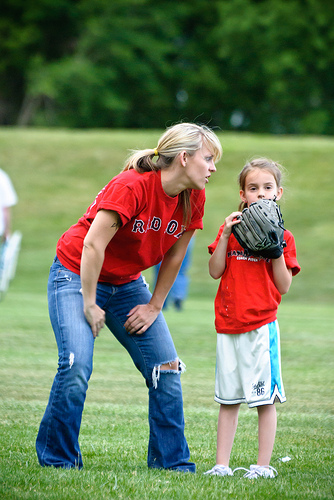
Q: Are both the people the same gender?
A: Yes, all the people are female.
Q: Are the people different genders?
A: No, all the people are female.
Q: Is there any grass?
A: Yes, there is grass.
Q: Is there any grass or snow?
A: Yes, there is grass.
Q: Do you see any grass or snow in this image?
A: Yes, there is grass.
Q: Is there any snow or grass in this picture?
A: Yes, there is grass.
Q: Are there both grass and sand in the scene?
A: No, there is grass but no sand.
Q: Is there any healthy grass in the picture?
A: Yes, there is healthy grass.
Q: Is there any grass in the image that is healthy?
A: Yes, there is grass that is healthy.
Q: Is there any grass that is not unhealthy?
A: Yes, there is healthy grass.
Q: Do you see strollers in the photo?
A: No, there are no strollers.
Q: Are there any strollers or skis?
A: No, there are no strollers or skis.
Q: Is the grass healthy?
A: Yes, the grass is healthy.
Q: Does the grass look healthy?
A: Yes, the grass is healthy.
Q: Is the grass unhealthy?
A: No, the grass is healthy.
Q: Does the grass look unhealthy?
A: No, the grass is healthy.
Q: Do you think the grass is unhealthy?
A: No, the grass is healthy.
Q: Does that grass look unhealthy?
A: No, the grass is healthy.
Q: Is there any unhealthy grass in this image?
A: No, there is grass but it is healthy.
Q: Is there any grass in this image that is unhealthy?
A: No, there is grass but it is healthy.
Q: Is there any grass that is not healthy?
A: No, there is grass but it is healthy.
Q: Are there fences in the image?
A: No, there are no fences.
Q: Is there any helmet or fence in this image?
A: No, there are no fences or helmets.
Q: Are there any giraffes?
A: No, there are no giraffes.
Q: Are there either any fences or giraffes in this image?
A: No, there are no giraffes or fences.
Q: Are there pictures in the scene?
A: No, there are no pictures.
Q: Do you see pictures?
A: No, there are no pictures.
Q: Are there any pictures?
A: No, there are no pictures.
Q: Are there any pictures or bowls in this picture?
A: No, there are no pictures or bowls.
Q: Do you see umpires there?
A: No, there are no umpires.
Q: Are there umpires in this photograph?
A: No, there are no umpires.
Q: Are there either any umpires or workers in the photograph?
A: No, there are no umpires or workers.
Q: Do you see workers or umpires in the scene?
A: No, there are no umpires or workers.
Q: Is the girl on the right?
A: Yes, the girl is on the right of the image.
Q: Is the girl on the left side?
A: No, the girl is on the right of the image.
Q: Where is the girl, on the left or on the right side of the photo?
A: The girl is on the right of the image.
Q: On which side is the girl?
A: The girl is on the right of the image.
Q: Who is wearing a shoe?
A: The girl is wearing a shoe.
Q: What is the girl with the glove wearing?
A: The girl is wearing a shoe.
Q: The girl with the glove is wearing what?
A: The girl is wearing a shoe.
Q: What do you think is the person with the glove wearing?
A: The girl is wearing a shoe.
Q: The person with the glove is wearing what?
A: The girl is wearing a shoe.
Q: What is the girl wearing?
A: The girl is wearing a shoe.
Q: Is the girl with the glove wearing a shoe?
A: Yes, the girl is wearing a shoe.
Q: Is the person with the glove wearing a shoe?
A: Yes, the girl is wearing a shoe.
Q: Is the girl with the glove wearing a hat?
A: No, the girl is wearing a shoe.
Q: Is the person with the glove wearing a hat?
A: No, the girl is wearing a shoe.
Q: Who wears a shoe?
A: The girl wears a shoe.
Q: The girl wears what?
A: The girl wears a shoe.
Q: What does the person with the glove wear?
A: The girl wears a shoe.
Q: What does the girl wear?
A: The girl wears a shoe.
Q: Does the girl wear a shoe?
A: Yes, the girl wears a shoe.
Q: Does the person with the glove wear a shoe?
A: Yes, the girl wears a shoe.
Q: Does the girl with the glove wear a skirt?
A: No, the girl wears a shoe.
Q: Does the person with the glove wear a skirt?
A: No, the girl wears a shoe.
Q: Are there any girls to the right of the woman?
A: Yes, there is a girl to the right of the woman.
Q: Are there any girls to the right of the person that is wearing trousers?
A: Yes, there is a girl to the right of the woman.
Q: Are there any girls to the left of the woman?
A: No, the girl is to the right of the woman.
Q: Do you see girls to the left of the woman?
A: No, the girl is to the right of the woman.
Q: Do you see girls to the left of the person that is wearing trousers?
A: No, the girl is to the right of the woman.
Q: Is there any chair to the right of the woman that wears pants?
A: No, there is a girl to the right of the woman.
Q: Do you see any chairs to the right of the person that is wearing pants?
A: No, there is a girl to the right of the woman.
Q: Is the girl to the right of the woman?
A: Yes, the girl is to the right of the woman.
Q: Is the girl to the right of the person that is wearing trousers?
A: Yes, the girl is to the right of the woman.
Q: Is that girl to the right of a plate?
A: No, the girl is to the right of the woman.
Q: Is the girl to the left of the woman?
A: No, the girl is to the right of the woman.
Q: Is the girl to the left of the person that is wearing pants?
A: No, the girl is to the right of the woman.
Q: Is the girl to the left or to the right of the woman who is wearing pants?
A: The girl is to the right of the woman.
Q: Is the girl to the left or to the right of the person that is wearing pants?
A: The girl is to the right of the woman.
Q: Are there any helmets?
A: No, there are no helmets.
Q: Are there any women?
A: Yes, there is a woman.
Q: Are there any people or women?
A: Yes, there is a woman.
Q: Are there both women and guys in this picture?
A: No, there is a woman but no guys.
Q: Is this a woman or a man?
A: This is a woman.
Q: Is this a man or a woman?
A: This is a woman.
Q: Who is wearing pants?
A: The woman is wearing pants.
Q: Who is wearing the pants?
A: The woman is wearing pants.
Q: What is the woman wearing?
A: The woman is wearing trousers.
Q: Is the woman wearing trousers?
A: Yes, the woman is wearing trousers.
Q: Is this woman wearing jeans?
A: No, the woman is wearing trousers.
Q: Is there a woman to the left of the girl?
A: Yes, there is a woman to the left of the girl.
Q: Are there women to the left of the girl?
A: Yes, there is a woman to the left of the girl.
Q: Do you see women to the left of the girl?
A: Yes, there is a woman to the left of the girl.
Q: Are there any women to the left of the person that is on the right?
A: Yes, there is a woman to the left of the girl.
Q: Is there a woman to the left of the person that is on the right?
A: Yes, there is a woman to the left of the girl.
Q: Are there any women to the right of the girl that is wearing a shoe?
A: No, the woman is to the left of the girl.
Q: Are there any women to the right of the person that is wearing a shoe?
A: No, the woman is to the left of the girl.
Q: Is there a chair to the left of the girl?
A: No, there is a woman to the left of the girl.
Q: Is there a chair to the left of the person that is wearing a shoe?
A: No, there is a woman to the left of the girl.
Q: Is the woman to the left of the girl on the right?
A: Yes, the woman is to the left of the girl.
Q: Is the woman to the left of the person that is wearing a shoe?
A: Yes, the woman is to the left of the girl.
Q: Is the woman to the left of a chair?
A: No, the woman is to the left of the girl.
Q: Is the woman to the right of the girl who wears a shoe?
A: No, the woman is to the left of the girl.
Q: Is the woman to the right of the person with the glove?
A: No, the woman is to the left of the girl.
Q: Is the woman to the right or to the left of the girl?
A: The woman is to the left of the girl.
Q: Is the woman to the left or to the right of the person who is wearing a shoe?
A: The woman is to the left of the girl.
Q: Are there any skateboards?
A: No, there are no skateboards.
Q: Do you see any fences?
A: No, there are no fences.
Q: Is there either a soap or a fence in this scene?
A: No, there are no fences or soaps.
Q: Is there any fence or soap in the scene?
A: No, there are no fences or soaps.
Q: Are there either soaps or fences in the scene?
A: No, there are no fences or soaps.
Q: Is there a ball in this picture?
A: No, there are no balls.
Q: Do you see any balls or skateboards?
A: No, there are no balls or skateboards.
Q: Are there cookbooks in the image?
A: No, there are no cookbooks.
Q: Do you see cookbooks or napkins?
A: No, there are no cookbooks or napkins.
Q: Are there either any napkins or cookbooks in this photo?
A: No, there are no cookbooks or napkins.